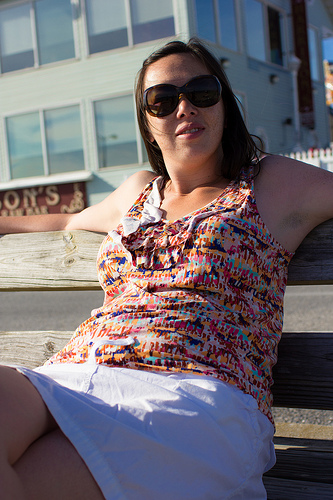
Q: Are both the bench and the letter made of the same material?
A: Yes, both the bench and the letter are made of wood.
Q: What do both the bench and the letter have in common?
A: The material, both the bench and the letter are wooden.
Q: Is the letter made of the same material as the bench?
A: Yes, both the letter and the bench are made of wood.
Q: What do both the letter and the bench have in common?
A: The material, both the letter and the bench are wooden.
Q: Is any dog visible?
A: No, there are no dogs.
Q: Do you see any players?
A: No, there are no players.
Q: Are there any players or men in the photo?
A: No, there are no players or men.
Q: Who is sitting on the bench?
A: The girl is sitting on the bench.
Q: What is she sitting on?
A: The girl is sitting on the bench.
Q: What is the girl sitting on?
A: The girl is sitting on the bench.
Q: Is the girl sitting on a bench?
A: Yes, the girl is sitting on a bench.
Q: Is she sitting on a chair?
A: No, the girl is sitting on a bench.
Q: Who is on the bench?
A: The girl is on the bench.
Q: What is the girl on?
A: The girl is on the bench.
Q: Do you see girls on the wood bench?
A: Yes, there is a girl on the bench.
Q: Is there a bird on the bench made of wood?
A: No, there is a girl on the bench.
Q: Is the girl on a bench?
A: Yes, the girl is on a bench.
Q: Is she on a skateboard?
A: No, the girl is on a bench.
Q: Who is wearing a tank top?
A: The girl is wearing a tank top.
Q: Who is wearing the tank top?
A: The girl is wearing a tank top.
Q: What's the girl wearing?
A: The girl is wearing a tank top.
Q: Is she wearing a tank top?
A: Yes, the girl is wearing a tank top.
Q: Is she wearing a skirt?
A: No, the girl is wearing a tank top.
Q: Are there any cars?
A: No, there are no cars.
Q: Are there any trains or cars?
A: No, there are no cars or trains.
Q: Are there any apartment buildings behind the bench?
A: Yes, there is an apartment building behind the bench.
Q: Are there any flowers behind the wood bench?
A: No, there is an apartment building behind the bench.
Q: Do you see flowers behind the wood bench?
A: No, there is an apartment building behind the bench.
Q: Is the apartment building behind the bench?
A: Yes, the apartment building is behind the bench.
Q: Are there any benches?
A: Yes, there is a bench.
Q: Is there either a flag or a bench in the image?
A: Yes, there is a bench.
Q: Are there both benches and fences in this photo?
A: Yes, there are both a bench and a fence.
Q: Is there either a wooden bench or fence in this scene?
A: Yes, there is a wood bench.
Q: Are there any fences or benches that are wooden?
A: Yes, the bench is wooden.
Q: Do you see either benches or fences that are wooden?
A: Yes, the bench is wooden.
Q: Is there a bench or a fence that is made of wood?
A: Yes, the bench is made of wood.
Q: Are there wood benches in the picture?
A: Yes, there is a wood bench.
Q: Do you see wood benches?
A: Yes, there is a wood bench.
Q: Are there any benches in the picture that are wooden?
A: Yes, there is a bench that is wooden.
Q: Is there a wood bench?
A: Yes, there is a bench that is made of wood.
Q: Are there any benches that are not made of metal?
A: Yes, there is a bench that is made of wood.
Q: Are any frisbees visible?
A: No, there are no frisbees.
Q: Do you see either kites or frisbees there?
A: No, there are no frisbees or kites.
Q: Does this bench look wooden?
A: Yes, the bench is wooden.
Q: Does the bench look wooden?
A: Yes, the bench is wooden.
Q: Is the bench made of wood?
A: Yes, the bench is made of wood.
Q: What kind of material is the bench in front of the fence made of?
A: The bench is made of wood.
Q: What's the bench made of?
A: The bench is made of wood.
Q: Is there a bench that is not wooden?
A: No, there is a bench but it is wooden.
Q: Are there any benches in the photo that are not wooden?
A: No, there is a bench but it is wooden.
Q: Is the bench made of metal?
A: No, the bench is made of wood.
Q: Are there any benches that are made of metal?
A: No, there is a bench but it is made of wood.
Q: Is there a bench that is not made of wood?
A: No, there is a bench but it is made of wood.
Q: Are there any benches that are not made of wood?
A: No, there is a bench but it is made of wood.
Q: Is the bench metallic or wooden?
A: The bench is wooden.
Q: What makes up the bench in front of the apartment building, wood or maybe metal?
A: The bench is made of wood.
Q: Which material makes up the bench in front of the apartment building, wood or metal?
A: The bench is made of wood.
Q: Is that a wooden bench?
A: Yes, that is a wooden bench.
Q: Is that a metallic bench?
A: No, that is a wooden bench.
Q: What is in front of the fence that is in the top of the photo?
A: The bench is in front of the fence.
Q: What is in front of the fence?
A: The bench is in front of the fence.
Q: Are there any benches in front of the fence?
A: Yes, there is a bench in front of the fence.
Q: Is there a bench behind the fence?
A: No, the bench is in front of the fence.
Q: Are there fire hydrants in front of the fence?
A: No, there is a bench in front of the fence.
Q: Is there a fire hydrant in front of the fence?
A: No, there is a bench in front of the fence.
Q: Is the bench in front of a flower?
A: No, the bench is in front of the fence.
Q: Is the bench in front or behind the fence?
A: The bench is in front of the fence.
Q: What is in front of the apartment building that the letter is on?
A: The bench is in front of the apartment building.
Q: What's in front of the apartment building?
A: The bench is in front of the apartment building.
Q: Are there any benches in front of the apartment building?
A: Yes, there is a bench in front of the apartment building.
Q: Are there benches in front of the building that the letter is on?
A: Yes, there is a bench in front of the apartment building.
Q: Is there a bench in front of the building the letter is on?
A: Yes, there is a bench in front of the apartment building.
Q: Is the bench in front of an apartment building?
A: Yes, the bench is in front of an apartment building.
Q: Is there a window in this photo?
A: Yes, there is a window.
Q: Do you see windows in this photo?
A: Yes, there is a window.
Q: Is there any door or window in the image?
A: Yes, there is a window.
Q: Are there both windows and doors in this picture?
A: No, there is a window but no doors.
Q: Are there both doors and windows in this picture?
A: No, there is a window but no doors.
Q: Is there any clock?
A: No, there are no clocks.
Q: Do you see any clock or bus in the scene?
A: No, there are no clocks or buses.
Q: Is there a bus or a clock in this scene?
A: No, there are no clocks or buses.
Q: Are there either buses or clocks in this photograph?
A: No, there are no clocks or buses.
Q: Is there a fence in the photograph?
A: Yes, there is a fence.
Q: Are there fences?
A: Yes, there is a fence.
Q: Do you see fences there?
A: Yes, there is a fence.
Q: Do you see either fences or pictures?
A: Yes, there is a fence.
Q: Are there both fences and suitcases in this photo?
A: No, there is a fence but no suitcases.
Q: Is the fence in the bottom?
A: No, the fence is in the top of the image.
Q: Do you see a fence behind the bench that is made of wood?
A: Yes, there is a fence behind the bench.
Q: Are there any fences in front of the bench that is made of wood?
A: No, the fence is behind the bench.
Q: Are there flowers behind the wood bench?
A: No, there is a fence behind the bench.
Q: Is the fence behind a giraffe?
A: No, the fence is behind a bench.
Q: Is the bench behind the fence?
A: No, the fence is behind the bench.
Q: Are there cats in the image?
A: No, there are no cats.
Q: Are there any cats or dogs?
A: No, there are no cats or dogs.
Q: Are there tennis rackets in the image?
A: No, there are no tennis rackets.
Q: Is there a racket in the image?
A: No, there are no rackets.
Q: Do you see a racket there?
A: No, there are no rackets.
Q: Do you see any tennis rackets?
A: No, there are no tennis rackets.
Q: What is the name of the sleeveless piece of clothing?
A: The clothing item is a tank top.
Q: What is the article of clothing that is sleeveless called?
A: The clothing item is a tank top.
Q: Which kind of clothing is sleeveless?
A: The clothing is a tank top.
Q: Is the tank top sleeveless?
A: Yes, the tank top is sleeveless.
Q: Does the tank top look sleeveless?
A: Yes, the tank top is sleeveless.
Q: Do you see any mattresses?
A: No, there are no mattresses.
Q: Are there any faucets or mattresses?
A: No, there are no mattresses or faucets.